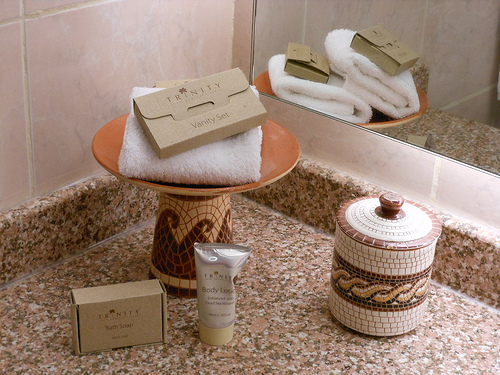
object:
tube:
[191, 241, 252, 346]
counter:
[1, 152, 499, 372]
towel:
[116, 85, 261, 184]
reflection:
[252, 24, 435, 151]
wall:
[2, 1, 252, 213]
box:
[68, 278, 170, 356]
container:
[327, 188, 442, 340]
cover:
[335, 191, 443, 251]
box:
[128, 65, 268, 160]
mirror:
[250, 1, 500, 179]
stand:
[90, 112, 300, 300]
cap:
[198, 323, 236, 346]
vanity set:
[190, 111, 231, 129]